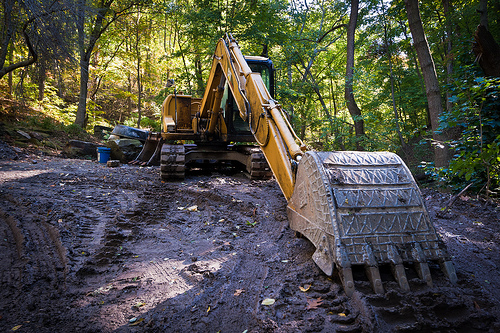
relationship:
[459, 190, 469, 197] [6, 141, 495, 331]
leaf on ground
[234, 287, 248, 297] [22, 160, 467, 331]
leaf on ground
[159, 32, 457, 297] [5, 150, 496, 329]
backhoe on dirt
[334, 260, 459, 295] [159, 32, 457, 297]
prongs of backhoe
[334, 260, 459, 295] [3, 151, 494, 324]
prongs sticking into mud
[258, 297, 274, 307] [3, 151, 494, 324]
leaf on mud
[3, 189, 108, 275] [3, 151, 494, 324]
tracks in mud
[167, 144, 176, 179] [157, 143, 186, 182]
mud on wheel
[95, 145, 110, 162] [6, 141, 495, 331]
buck on ground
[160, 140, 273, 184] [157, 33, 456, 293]
tracks moving backhoe